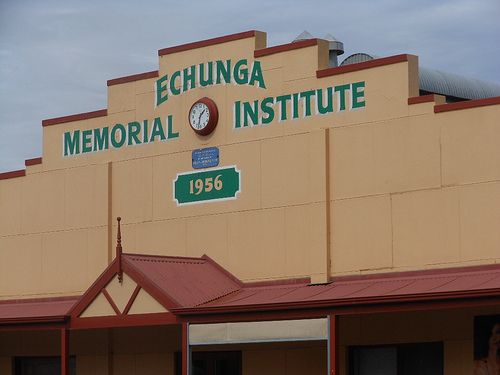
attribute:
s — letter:
[255, 95, 276, 125]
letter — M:
[59, 129, 83, 156]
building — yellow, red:
[4, 31, 498, 371]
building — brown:
[0, 30, 500, 290]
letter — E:
[76, 123, 100, 154]